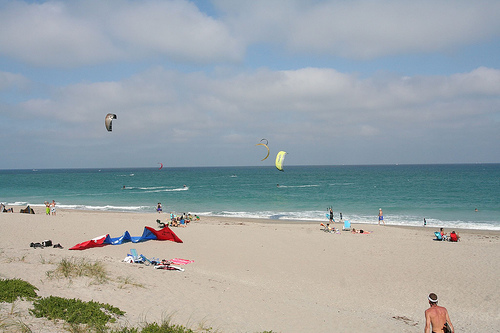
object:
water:
[3, 164, 499, 227]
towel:
[168, 256, 193, 267]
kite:
[269, 146, 293, 170]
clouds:
[0, 0, 498, 166]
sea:
[310, 169, 486, 199]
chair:
[125, 247, 153, 263]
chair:
[158, 256, 195, 267]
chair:
[341, 220, 351, 230]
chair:
[434, 230, 443, 239]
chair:
[449, 232, 457, 241]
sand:
[0, 203, 498, 331]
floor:
[3, 208, 499, 332]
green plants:
[28, 296, 120, 323]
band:
[424, 295, 440, 302]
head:
[426, 290, 439, 305]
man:
[417, 292, 458, 333]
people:
[433, 227, 462, 243]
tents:
[83, 221, 172, 248]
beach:
[0, 191, 498, 331]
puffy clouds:
[255, 69, 366, 127]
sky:
[3, 3, 499, 168]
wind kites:
[98, 112, 124, 133]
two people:
[40, 199, 60, 215]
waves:
[4, 193, 158, 214]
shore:
[0, 186, 496, 246]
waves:
[131, 175, 192, 205]